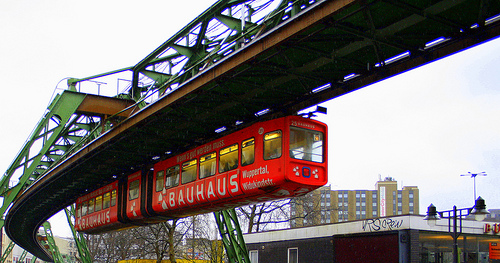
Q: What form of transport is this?
A: Subway.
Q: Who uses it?
A: Residents of this city.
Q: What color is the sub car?
A: Red.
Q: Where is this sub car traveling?
A: Over a city.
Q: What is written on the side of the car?
A: BAUHAUS.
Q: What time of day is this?
A: Dusk or dawn.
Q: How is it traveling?
A: The subway system.